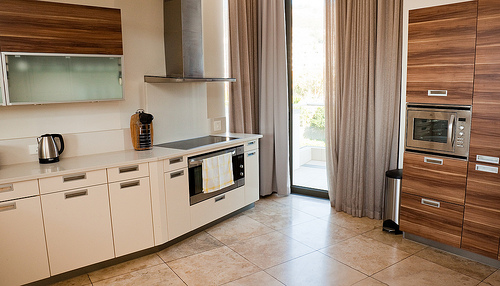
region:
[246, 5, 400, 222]
this is a door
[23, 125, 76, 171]
this is a kettle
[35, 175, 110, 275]
this are cabinet doors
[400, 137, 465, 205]
this are cabinet doors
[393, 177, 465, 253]
this are cabinet doors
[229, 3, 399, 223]
the curtains are beige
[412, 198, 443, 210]
Silver handle in the cabinet door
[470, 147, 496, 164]
Silver handle in the cabinet door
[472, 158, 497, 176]
Silver handle in the cabinet door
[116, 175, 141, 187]
Silver handle in the cabinet door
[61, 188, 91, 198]
Silver handle in the cabinet door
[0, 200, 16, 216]
Silver handle in the cabinet door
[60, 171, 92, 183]
Silver handle in the cabinet door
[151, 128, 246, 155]
black stove top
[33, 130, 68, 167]
silver kettle on the counter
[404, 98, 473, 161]
microwave set in the wall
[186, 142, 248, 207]
oven under the stove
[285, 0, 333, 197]
tall glass door in a kitchen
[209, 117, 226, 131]
electrical outlet by the stove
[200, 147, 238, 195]
white towel on the handle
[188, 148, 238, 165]
handle of the oven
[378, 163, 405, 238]
black and silver trash bin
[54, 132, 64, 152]
black handle on a kettle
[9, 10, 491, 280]
modern kitchen in white and brown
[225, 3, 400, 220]
beige draperies with many pleats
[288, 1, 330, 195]
winfodw showing terrace and plantings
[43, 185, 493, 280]
large square tiles covering floor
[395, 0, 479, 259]
silver microwave set into middle of wooden drawers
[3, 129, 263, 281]
long white counter with drawers, stove and oven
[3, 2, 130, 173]
wood and frosted glass cabinets over counter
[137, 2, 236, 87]
large metal pipe for exhaust fan with thin panel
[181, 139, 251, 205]
dish towel folded over oven handle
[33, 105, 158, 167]
silver and yellow appliances on counter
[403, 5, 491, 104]
A wood paneled drawer.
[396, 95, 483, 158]
A small microwave oven.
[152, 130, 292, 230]
A metal stove top.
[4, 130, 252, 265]
Cream colored kitchen counter.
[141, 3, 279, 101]
Ventilation duct for the oven.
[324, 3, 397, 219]
Long sliding window drapes.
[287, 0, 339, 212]
A full size glass door.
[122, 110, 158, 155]
A kitchen utensil rack.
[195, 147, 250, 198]
A towel on the stove door.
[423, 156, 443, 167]
silver colored cabinet handle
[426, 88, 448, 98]
silver colored cabinet handle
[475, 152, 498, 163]
silver colored cabinet handle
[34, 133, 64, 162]
pot is on top of the counter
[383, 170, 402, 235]
trash can is beside curtain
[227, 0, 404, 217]
curtain is covering window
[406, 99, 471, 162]
microwave is attached to wall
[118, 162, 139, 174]
handle is silver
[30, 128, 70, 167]
silver coffee pot on kitchen counter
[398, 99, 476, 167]
silver microwave in wooden wall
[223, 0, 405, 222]
beige curtains covering wall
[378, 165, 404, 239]
silver trash can on floor next to microwave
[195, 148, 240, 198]
towel on handlebar of oven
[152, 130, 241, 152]
electric stove range top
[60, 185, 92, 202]
silver handle on cabinet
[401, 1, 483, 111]
wooden cabinet door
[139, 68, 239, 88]
metal shelf on wall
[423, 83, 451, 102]
metal handle on wooden cabinet